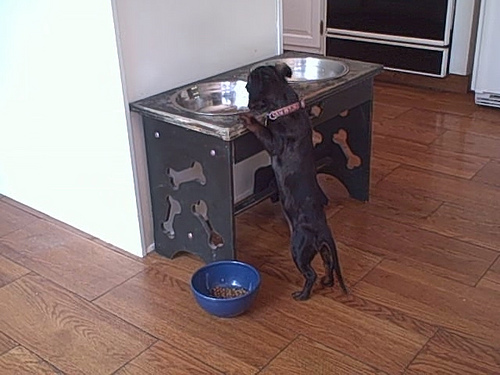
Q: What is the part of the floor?
A: Wooden.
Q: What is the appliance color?
A: Black and white.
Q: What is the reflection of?
A: Wooden floor.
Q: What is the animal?
A: Dog.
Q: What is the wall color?
A: White.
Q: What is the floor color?
A: Brown.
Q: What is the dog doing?
A: Standing on floor.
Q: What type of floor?
A: Wooden.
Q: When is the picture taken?
A: During the day.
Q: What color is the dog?
A: Black.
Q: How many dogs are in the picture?
A: One.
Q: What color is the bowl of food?
A: Blue.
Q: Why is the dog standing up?
A: To reach his bowl.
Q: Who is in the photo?
A: The dog.